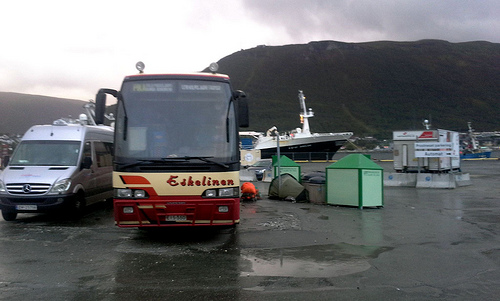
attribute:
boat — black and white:
[257, 88, 354, 159]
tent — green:
[323, 151, 385, 209]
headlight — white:
[202, 182, 238, 197]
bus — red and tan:
[89, 68, 255, 230]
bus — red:
[93, 60, 249, 230]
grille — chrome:
[4, 179, 50, 199]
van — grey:
[0, 119, 117, 217]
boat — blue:
[259, 130, 352, 153]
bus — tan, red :
[84, 60, 294, 269]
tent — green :
[272, 105, 423, 215]